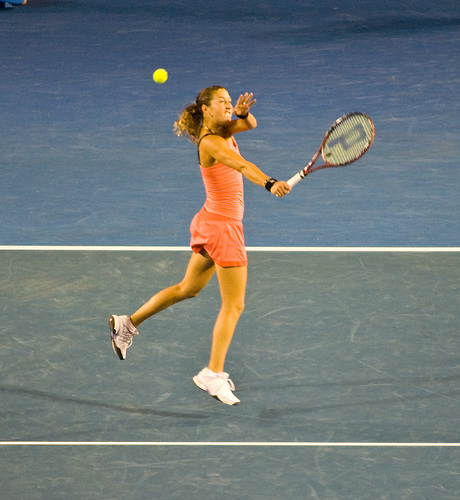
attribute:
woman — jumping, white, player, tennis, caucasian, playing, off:
[107, 82, 378, 409]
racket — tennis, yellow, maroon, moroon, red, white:
[271, 109, 378, 199]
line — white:
[1, 240, 459, 256]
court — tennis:
[1, 2, 456, 494]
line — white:
[1, 437, 459, 452]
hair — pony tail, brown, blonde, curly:
[172, 83, 236, 143]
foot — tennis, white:
[189, 362, 245, 408]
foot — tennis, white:
[106, 310, 143, 363]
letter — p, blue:
[326, 120, 368, 154]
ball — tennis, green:
[151, 67, 170, 86]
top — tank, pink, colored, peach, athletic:
[193, 130, 248, 223]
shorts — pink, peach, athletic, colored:
[184, 203, 252, 271]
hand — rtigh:
[267, 175, 292, 200]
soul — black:
[189, 374, 243, 416]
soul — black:
[103, 312, 129, 364]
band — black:
[263, 171, 279, 193]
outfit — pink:
[185, 136, 254, 270]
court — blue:
[0, 1, 458, 243]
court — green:
[1, 251, 459, 499]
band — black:
[235, 108, 256, 122]